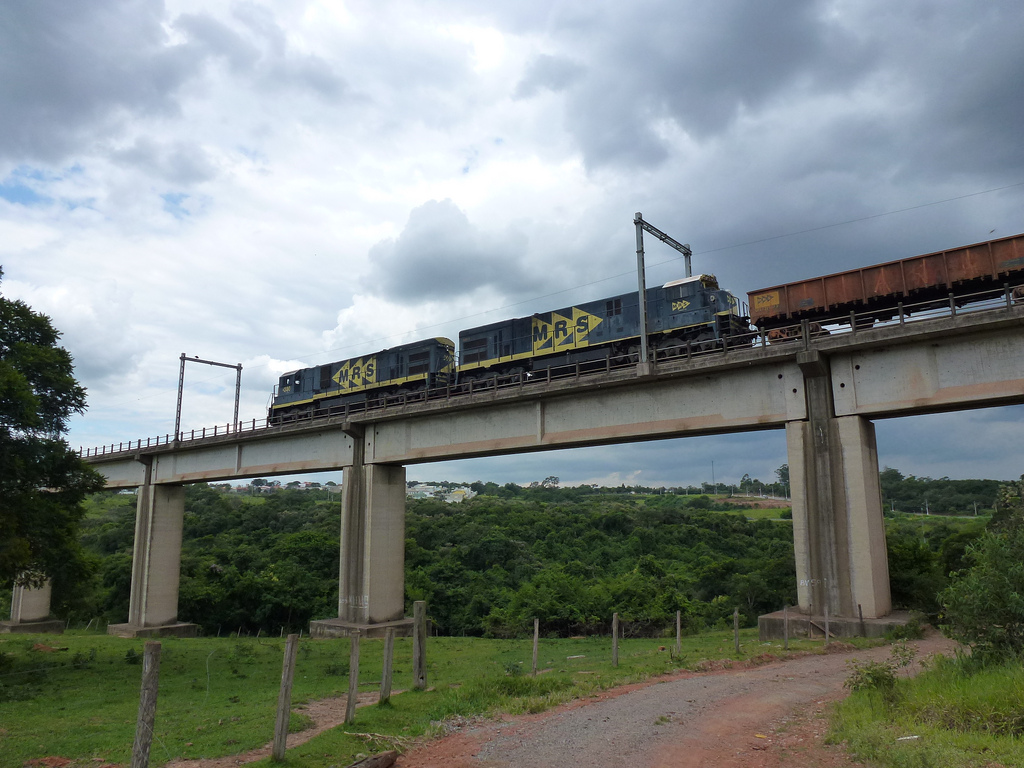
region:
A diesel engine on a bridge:
[261, 336, 457, 426]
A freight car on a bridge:
[749, 231, 1019, 337]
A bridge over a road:
[77, 291, 1019, 633]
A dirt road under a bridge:
[390, 638, 985, 756]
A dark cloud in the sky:
[340, 184, 572, 322]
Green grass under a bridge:
[9, 619, 899, 757]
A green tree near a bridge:
[5, 285, 104, 596]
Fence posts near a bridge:
[119, 611, 432, 763]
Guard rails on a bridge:
[69, 412, 276, 460]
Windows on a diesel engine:
[660, 276, 698, 303]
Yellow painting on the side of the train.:
[318, 353, 388, 411]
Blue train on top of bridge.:
[275, 265, 719, 367]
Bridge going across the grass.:
[78, 391, 1017, 604]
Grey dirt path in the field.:
[532, 651, 967, 765]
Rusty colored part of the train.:
[748, 268, 1008, 320]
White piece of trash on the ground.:
[886, 733, 921, 753]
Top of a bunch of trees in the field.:
[500, 476, 798, 607]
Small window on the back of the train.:
[590, 291, 628, 326]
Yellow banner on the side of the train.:
[751, 280, 797, 318]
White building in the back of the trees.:
[403, 473, 470, 508]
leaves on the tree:
[466, 590, 490, 616]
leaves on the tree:
[532, 543, 567, 556]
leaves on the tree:
[939, 593, 993, 631]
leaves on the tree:
[203, 579, 249, 611]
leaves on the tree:
[620, 528, 703, 566]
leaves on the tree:
[636, 514, 638, 516]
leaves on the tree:
[465, 515, 488, 545]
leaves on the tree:
[267, 499, 318, 541]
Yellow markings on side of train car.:
[332, 356, 386, 385]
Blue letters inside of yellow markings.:
[332, 361, 383, 378]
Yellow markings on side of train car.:
[522, 309, 599, 349]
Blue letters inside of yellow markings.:
[533, 309, 591, 341]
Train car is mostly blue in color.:
[272, 348, 451, 410]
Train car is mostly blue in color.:
[446, 275, 726, 346]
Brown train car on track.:
[746, 237, 1007, 321]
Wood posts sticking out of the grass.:
[114, 629, 462, 740]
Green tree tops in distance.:
[180, 483, 762, 614]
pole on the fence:
[124, 708, 160, 751]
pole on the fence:
[261, 693, 297, 739]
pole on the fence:
[607, 632, 628, 678]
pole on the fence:
[719, 613, 749, 633]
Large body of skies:
[234, 34, 507, 227]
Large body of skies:
[578, 42, 797, 202]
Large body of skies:
[261, 59, 533, 257]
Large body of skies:
[19, 38, 289, 231]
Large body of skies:
[410, 64, 614, 202]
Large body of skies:
[54, 32, 371, 247]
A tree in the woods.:
[443, 539, 526, 613]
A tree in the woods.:
[533, 533, 588, 631]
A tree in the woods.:
[600, 569, 651, 639]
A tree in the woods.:
[887, 514, 941, 601]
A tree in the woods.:
[916, 510, 952, 564]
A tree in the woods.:
[223, 516, 331, 622]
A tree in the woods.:
[187, 542, 273, 615]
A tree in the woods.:
[256, 560, 313, 614]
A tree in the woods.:
[69, 547, 126, 596]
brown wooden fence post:
[133, 642, 162, 759]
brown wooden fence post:
[266, 631, 309, 762]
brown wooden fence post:
[341, 626, 362, 719]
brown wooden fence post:
[375, 628, 399, 704]